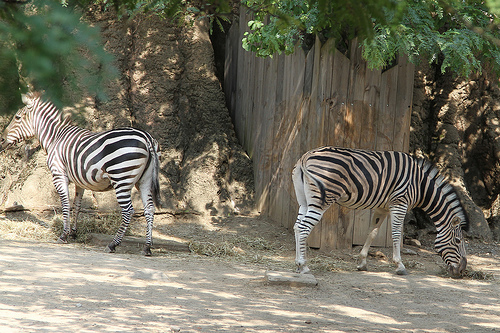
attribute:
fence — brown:
[227, 6, 419, 250]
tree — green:
[210, 16, 498, 252]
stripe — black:
[305, 155, 363, 206]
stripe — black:
[298, 246, 305, 254]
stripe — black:
[309, 193, 329, 205]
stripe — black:
[308, 207, 322, 214]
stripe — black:
[303, 213, 320, 221]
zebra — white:
[14, 86, 175, 251]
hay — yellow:
[190, 219, 285, 261]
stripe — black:
[104, 151, 151, 164]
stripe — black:
[94, 138, 137, 158]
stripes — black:
[312, 157, 428, 195]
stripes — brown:
[302, 152, 430, 198]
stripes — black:
[312, 156, 430, 211]